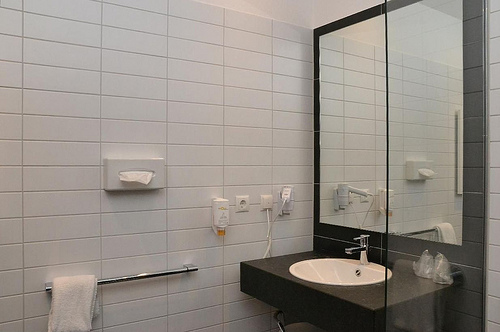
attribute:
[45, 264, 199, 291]
rack — metallic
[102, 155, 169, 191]
box — white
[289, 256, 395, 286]
sink — white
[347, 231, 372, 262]
faucet — metallic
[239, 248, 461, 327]
counter — black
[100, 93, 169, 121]
tile — white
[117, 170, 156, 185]
napkin — white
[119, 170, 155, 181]
napkin — white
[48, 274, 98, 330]
towel — white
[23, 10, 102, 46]
tile — white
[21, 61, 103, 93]
tile — white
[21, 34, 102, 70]
tile — white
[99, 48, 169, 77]
tile — white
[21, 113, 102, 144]
tile — white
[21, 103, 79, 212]
tile — white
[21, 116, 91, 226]
tile — white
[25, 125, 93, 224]
tile — white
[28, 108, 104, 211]
tile — white